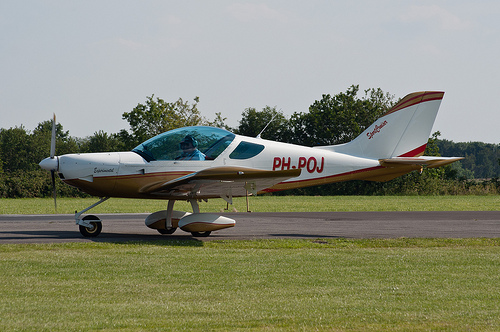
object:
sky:
[0, 0, 499, 144]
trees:
[1, 83, 496, 197]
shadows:
[2, 230, 203, 247]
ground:
[0, 211, 500, 243]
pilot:
[175, 134, 207, 161]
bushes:
[0, 123, 31, 172]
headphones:
[184, 133, 198, 147]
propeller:
[50, 113, 57, 211]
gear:
[143, 210, 236, 237]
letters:
[273, 156, 325, 173]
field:
[0, 237, 500, 326]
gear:
[79, 210, 236, 237]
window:
[229, 141, 266, 160]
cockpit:
[132, 126, 236, 163]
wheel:
[190, 229, 211, 237]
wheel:
[157, 227, 177, 235]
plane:
[38, 90, 465, 239]